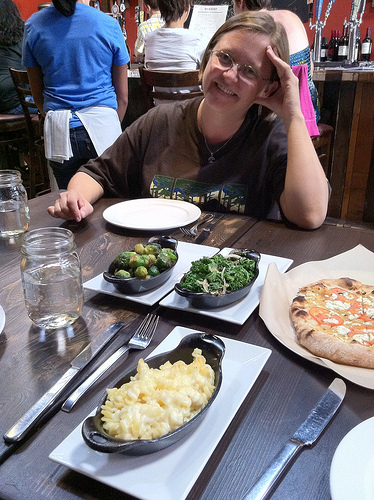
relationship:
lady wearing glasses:
[48, 12, 328, 230] [211, 51, 278, 82]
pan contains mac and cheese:
[84, 332, 226, 457] [101, 349, 215, 440]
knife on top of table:
[243, 377, 346, 499] [1, 190, 372, 500]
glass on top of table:
[21, 227, 84, 331] [1, 190, 372, 500]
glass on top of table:
[1, 169, 28, 233] [1, 190, 372, 500]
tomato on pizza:
[313, 306, 340, 324] [291, 278, 373, 369]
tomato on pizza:
[310, 288, 373, 347] [291, 278, 373, 369]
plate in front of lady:
[105, 195, 200, 229] [48, 12, 328, 230]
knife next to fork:
[5, 299, 123, 444] [63, 311, 158, 411]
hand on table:
[47, 193, 95, 224] [1, 190, 372, 500]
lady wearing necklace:
[48, 12, 328, 230] [197, 107, 236, 162]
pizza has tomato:
[291, 278, 373, 369] [313, 306, 340, 324]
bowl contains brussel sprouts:
[104, 234, 179, 292] [111, 243, 177, 279]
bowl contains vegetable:
[173, 247, 261, 304] [184, 256, 257, 296]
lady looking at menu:
[143, 1, 207, 107] [188, 5, 229, 32]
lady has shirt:
[48, 12, 328, 230] [76, 95, 332, 227]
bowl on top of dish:
[104, 234, 179, 292] [80, 238, 220, 306]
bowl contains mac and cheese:
[104, 234, 179, 292] [101, 349, 215, 440]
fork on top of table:
[63, 311, 158, 411] [1, 190, 372, 500]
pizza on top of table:
[291, 278, 373, 369] [1, 190, 372, 500]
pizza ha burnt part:
[291, 278, 373, 369] [293, 295, 314, 340]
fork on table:
[63, 311, 158, 411] [1, 190, 372, 500]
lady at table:
[48, 12, 328, 230] [1, 190, 372, 500]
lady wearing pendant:
[48, 12, 328, 230] [208, 157, 214, 164]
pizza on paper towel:
[291, 278, 373, 369] [261, 243, 373, 394]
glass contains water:
[21, 227, 84, 331] [25, 271, 85, 326]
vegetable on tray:
[184, 256, 257, 296] [161, 245, 294, 325]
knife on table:
[243, 377, 346, 499] [1, 190, 372, 500]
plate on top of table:
[105, 195, 200, 229] [1, 190, 372, 500]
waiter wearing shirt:
[23, 1, 130, 187] [23, 4, 131, 128]